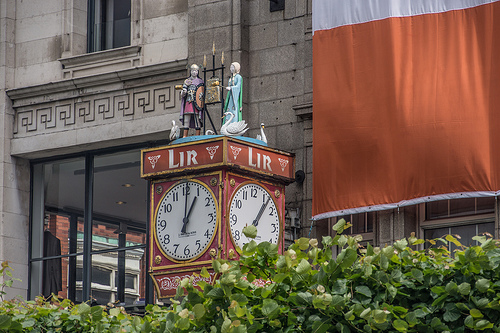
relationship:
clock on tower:
[144, 179, 217, 261] [208, 172, 241, 185]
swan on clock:
[221, 111, 255, 137] [144, 179, 217, 261]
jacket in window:
[332, 82, 381, 106] [103, 259, 129, 299]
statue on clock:
[184, 71, 208, 121] [144, 179, 217, 261]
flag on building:
[334, 3, 394, 32] [247, 24, 273, 49]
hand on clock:
[179, 208, 201, 230] [144, 179, 217, 261]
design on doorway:
[136, 95, 158, 121] [18, 120, 67, 287]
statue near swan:
[184, 71, 208, 121] [221, 111, 255, 137]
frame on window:
[103, 145, 142, 149] [103, 259, 129, 299]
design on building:
[136, 95, 158, 121] [247, 24, 273, 49]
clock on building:
[144, 179, 217, 261] [247, 24, 273, 49]